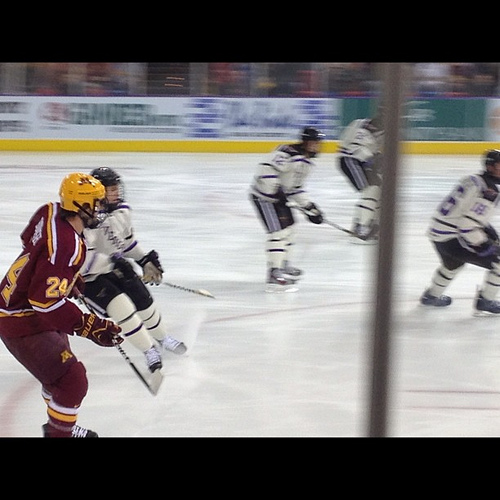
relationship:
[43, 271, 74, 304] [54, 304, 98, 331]
number on sleeve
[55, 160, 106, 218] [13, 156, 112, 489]
helmet on hockey player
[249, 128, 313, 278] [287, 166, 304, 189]
hockey player in white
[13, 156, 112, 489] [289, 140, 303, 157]
hockey player in black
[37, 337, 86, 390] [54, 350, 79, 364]
pants leg has m logo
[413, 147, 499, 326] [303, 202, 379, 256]
player holding hockey stick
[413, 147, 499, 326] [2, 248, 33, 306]
player has number 4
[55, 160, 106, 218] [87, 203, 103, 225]
helmet has cage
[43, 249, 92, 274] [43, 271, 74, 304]
jersey has 24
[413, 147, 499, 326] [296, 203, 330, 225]
player wearing gloves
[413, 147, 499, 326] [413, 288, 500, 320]
player wearing skates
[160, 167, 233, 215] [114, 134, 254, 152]
rink has yellow stripe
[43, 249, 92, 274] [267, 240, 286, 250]
jersey has stripes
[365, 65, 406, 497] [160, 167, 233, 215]
pole on rink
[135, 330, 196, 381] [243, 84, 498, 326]
ice skates on players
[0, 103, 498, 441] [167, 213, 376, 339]
men playing hockey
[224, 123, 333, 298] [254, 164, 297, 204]
man slightly hunched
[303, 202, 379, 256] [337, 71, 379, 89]
hockey stick lifted in air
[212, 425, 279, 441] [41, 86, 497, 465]
edge of arena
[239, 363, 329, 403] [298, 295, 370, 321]
ice has scratch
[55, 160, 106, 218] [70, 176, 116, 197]
helmet on head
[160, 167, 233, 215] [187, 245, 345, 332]
rink for ice skating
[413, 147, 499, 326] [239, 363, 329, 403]
player skating on ice